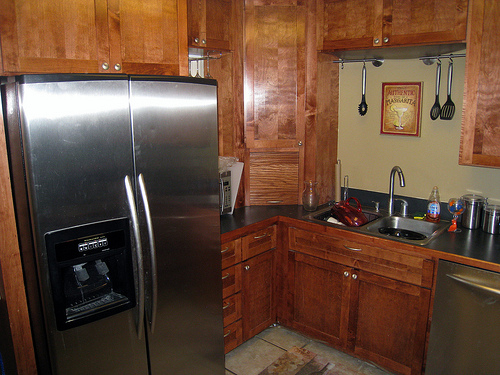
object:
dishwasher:
[421, 256, 498, 374]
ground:
[267, 326, 288, 346]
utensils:
[440, 42, 456, 122]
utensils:
[439, 48, 457, 122]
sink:
[427, 204, 441, 215]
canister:
[482, 202, 496, 234]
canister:
[456, 189, 486, 236]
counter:
[431, 232, 466, 250]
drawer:
[289, 228, 434, 282]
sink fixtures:
[383, 163, 409, 220]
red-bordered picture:
[379, 79, 425, 138]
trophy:
[390, 101, 411, 129]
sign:
[380, 85, 419, 138]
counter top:
[220, 200, 498, 263]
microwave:
[217, 156, 244, 216]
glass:
[443, 193, 468, 238]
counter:
[479, 232, 498, 261]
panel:
[222, 185, 233, 212]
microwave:
[217, 152, 243, 217]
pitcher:
[330, 192, 368, 228]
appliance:
[1, 68, 224, 373]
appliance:
[420, 256, 499, 374]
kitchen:
[429, 48, 445, 128]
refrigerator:
[6, 72, 224, 372]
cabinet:
[239, 7, 309, 208]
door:
[126, 74, 226, 374]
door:
[3, 72, 150, 372]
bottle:
[424, 185, 441, 222]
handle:
[444, 62, 456, 95]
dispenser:
[48, 212, 134, 329]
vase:
[299, 177, 323, 214]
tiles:
[224, 356, 245, 372]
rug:
[276, 343, 316, 371]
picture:
[377, 80, 427, 137]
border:
[349, 198, 381, 218]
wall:
[350, 138, 392, 160]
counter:
[219, 206, 251, 232]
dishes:
[328, 195, 368, 228]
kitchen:
[354, 60, 372, 119]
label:
[425, 186, 446, 219]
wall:
[422, 132, 453, 164]